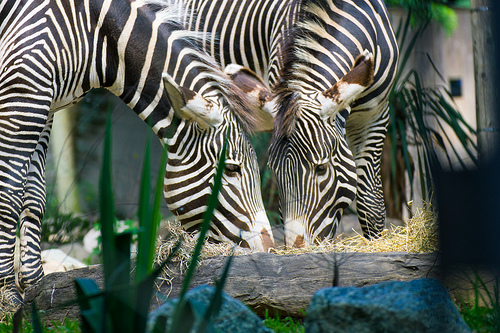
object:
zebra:
[0, 0, 275, 317]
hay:
[279, 212, 446, 254]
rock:
[303, 279, 470, 332]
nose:
[245, 218, 275, 253]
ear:
[318, 54, 376, 115]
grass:
[0, 101, 498, 333]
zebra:
[157, 0, 400, 252]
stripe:
[132, 21, 180, 114]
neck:
[95, 0, 227, 143]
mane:
[273, 1, 301, 141]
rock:
[24, 251, 437, 317]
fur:
[21, 12, 71, 67]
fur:
[213, 0, 274, 43]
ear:
[159, 70, 222, 127]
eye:
[223, 161, 242, 177]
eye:
[315, 162, 329, 175]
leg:
[0, 88, 46, 318]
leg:
[18, 112, 54, 300]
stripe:
[107, 0, 129, 88]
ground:
[0, 213, 498, 331]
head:
[160, 124, 275, 253]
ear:
[223, 62, 275, 116]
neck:
[266, 1, 365, 96]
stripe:
[293, 11, 361, 63]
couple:
[2, 1, 400, 313]